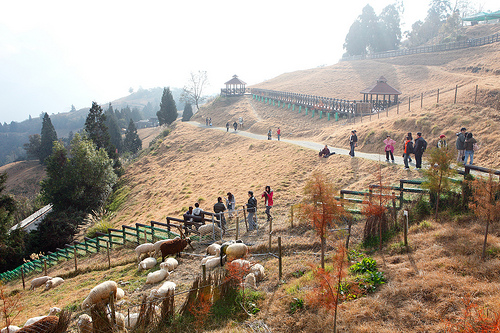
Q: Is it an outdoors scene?
A: Yes, it is outdoors.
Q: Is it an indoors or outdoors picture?
A: It is outdoors.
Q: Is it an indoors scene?
A: No, it is outdoors.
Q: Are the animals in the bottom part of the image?
A: Yes, the animals are in the bottom of the image.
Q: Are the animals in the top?
A: No, the animals are in the bottom of the image.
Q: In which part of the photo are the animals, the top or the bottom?
A: The animals are in the bottom of the image.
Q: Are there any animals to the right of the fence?
A: Yes, there are animals to the right of the fence.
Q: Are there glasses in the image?
A: No, there are no glasses.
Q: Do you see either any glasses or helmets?
A: No, there are no glasses or helmets.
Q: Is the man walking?
A: Yes, the man is walking.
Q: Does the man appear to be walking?
A: Yes, the man is walking.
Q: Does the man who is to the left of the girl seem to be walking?
A: Yes, the man is walking.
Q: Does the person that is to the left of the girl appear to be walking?
A: Yes, the man is walking.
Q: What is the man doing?
A: The man is walking.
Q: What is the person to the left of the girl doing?
A: The man is walking.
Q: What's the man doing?
A: The man is walking.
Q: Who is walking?
A: The man is walking.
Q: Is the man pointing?
A: No, the man is walking.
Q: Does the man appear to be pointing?
A: No, the man is walking.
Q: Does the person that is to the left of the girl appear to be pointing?
A: No, the man is walking.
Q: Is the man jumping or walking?
A: The man is walking.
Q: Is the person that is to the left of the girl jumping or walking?
A: The man is walking.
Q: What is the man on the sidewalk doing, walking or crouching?
A: The man is walking.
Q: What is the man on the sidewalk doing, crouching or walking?
A: The man is walking.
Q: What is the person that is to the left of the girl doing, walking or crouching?
A: The man is walking.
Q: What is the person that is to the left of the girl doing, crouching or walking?
A: The man is walking.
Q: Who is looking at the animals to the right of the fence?
A: The man is looking at the animals.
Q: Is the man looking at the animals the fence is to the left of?
A: Yes, the man is looking at the animals.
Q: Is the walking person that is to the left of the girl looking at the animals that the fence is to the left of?
A: Yes, the man is looking at the animals.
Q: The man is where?
A: The man is on the sidewalk.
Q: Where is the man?
A: The man is on the sidewalk.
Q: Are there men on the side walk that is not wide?
A: Yes, there is a man on the sidewalk.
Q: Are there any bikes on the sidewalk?
A: No, there is a man on the sidewalk.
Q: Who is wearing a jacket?
A: The man is wearing a jacket.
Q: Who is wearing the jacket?
A: The man is wearing a jacket.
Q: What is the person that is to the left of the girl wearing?
A: The man is wearing a jacket.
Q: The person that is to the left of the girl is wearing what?
A: The man is wearing a jacket.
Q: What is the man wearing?
A: The man is wearing a jacket.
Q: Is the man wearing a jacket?
A: Yes, the man is wearing a jacket.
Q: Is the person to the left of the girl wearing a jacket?
A: Yes, the man is wearing a jacket.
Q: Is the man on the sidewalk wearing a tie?
A: No, the man is wearing a jacket.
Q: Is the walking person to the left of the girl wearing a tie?
A: No, the man is wearing a jacket.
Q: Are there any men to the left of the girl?
A: Yes, there is a man to the left of the girl.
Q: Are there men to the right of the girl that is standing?
A: No, the man is to the left of the girl.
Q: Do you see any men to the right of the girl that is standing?
A: No, the man is to the left of the girl.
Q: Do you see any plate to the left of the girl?
A: No, there is a man to the left of the girl.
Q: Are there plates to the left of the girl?
A: No, there is a man to the left of the girl.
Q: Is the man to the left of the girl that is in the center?
A: Yes, the man is to the left of the girl.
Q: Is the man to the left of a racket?
A: No, the man is to the left of the girl.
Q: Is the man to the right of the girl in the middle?
A: No, the man is to the left of the girl.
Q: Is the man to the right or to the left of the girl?
A: The man is to the left of the girl.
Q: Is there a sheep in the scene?
A: Yes, there is a sheep.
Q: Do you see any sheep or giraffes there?
A: Yes, there is a sheep.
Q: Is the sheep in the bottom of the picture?
A: Yes, the sheep is in the bottom of the image.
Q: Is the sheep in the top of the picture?
A: No, the sheep is in the bottom of the image.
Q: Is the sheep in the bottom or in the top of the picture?
A: The sheep is in the bottom of the image.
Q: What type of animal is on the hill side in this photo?
A: The animal is a sheep.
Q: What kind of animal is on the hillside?
A: The animal is a sheep.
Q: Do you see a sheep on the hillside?
A: Yes, there is a sheep on the hillside.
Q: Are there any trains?
A: No, there are no trains.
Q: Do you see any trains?
A: No, there are no trains.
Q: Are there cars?
A: No, there are no cars.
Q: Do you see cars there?
A: No, there are no cars.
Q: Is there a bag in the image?
A: No, there are no bags.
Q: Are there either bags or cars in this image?
A: No, there are no bags or cars.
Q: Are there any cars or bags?
A: No, there are no bags or cars.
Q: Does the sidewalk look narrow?
A: Yes, the sidewalk is narrow.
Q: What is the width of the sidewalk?
A: The sidewalk is narrow.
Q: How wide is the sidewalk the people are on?
A: The sidewalk is narrow.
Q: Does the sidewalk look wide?
A: No, the sidewalk is narrow.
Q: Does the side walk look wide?
A: No, the side walk is narrow.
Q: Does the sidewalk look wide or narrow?
A: The sidewalk is narrow.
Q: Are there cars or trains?
A: No, there are no cars or trains.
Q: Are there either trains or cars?
A: No, there are no cars or trains.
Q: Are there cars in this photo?
A: No, there are no cars.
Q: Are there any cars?
A: No, there are no cars.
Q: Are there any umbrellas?
A: No, there are no umbrellas.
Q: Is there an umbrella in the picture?
A: No, there are no umbrellas.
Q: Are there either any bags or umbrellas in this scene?
A: No, there are no umbrellas or bags.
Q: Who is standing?
A: The people are standing.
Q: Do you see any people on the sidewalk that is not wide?
A: Yes, there are people on the sidewalk.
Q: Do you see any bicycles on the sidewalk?
A: No, there are people on the sidewalk.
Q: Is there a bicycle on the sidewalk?
A: No, there are people on the sidewalk.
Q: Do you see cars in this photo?
A: No, there are no cars.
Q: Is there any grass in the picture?
A: Yes, there is grass.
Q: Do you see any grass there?
A: Yes, there is grass.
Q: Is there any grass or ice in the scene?
A: Yes, there is grass.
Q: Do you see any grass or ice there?
A: Yes, there is grass.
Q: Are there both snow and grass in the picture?
A: No, there is grass but no snow.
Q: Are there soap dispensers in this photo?
A: No, there are no soap dispensers.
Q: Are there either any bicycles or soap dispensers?
A: No, there are no soap dispensers or bicycles.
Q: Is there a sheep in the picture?
A: Yes, there is a sheep.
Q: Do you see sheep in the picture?
A: Yes, there is a sheep.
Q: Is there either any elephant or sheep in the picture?
A: Yes, there is a sheep.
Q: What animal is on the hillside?
A: The animal is a sheep.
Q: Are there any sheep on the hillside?
A: Yes, there is a sheep on the hillside.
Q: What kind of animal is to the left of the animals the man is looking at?
A: The animal is a sheep.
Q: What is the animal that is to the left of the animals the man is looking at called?
A: The animal is a sheep.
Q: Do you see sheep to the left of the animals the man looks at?
A: Yes, there is a sheep to the left of the animals.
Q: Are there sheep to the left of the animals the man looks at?
A: Yes, there is a sheep to the left of the animals.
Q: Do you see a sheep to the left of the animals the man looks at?
A: Yes, there is a sheep to the left of the animals.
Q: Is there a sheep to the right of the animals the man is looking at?
A: No, the sheep is to the left of the animals.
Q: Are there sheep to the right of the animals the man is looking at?
A: No, the sheep is to the left of the animals.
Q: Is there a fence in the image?
A: Yes, there is a fence.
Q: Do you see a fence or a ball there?
A: Yes, there is a fence.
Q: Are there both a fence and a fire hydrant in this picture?
A: No, there is a fence but no fire hydrants.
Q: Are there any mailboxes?
A: No, there are no mailboxes.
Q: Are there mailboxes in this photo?
A: No, there are no mailboxes.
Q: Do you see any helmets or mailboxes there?
A: No, there are no mailboxes or helmets.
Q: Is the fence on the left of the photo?
A: Yes, the fence is on the left of the image.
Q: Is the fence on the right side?
A: No, the fence is on the left of the image.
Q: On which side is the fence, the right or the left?
A: The fence is on the left of the image.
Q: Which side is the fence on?
A: The fence is on the left of the image.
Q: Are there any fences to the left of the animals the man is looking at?
A: Yes, there is a fence to the left of the animals.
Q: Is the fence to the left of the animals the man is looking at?
A: Yes, the fence is to the left of the animals.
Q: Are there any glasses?
A: No, there are no glasses.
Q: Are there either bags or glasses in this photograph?
A: No, there are no glasses or bags.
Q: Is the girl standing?
A: Yes, the girl is standing.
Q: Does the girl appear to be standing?
A: Yes, the girl is standing.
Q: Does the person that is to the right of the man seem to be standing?
A: Yes, the girl is standing.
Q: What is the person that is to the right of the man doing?
A: The girl is standing.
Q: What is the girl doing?
A: The girl is standing.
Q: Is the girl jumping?
A: No, the girl is standing.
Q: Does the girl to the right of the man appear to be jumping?
A: No, the girl is standing.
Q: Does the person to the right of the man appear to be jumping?
A: No, the girl is standing.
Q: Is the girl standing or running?
A: The girl is standing.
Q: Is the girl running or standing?
A: The girl is standing.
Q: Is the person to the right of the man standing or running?
A: The girl is standing.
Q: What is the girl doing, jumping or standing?
A: The girl is standing.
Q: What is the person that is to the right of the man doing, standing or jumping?
A: The girl is standing.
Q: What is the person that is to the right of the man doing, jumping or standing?
A: The girl is standing.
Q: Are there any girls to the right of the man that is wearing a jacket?
A: Yes, there is a girl to the right of the man.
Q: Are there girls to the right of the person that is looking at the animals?
A: Yes, there is a girl to the right of the man.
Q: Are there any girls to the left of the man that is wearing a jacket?
A: No, the girl is to the right of the man.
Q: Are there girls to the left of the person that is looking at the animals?
A: No, the girl is to the right of the man.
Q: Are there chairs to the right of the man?
A: No, there is a girl to the right of the man.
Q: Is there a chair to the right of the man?
A: No, there is a girl to the right of the man.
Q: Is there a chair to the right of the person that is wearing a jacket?
A: No, there is a girl to the right of the man.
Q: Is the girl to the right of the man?
A: Yes, the girl is to the right of the man.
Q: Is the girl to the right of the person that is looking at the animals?
A: Yes, the girl is to the right of the man.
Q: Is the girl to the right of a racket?
A: No, the girl is to the right of the man.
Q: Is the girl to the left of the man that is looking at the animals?
A: No, the girl is to the right of the man.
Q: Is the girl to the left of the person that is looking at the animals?
A: No, the girl is to the right of the man.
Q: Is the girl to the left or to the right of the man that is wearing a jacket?
A: The girl is to the right of the man.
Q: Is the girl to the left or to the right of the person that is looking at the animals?
A: The girl is to the right of the man.